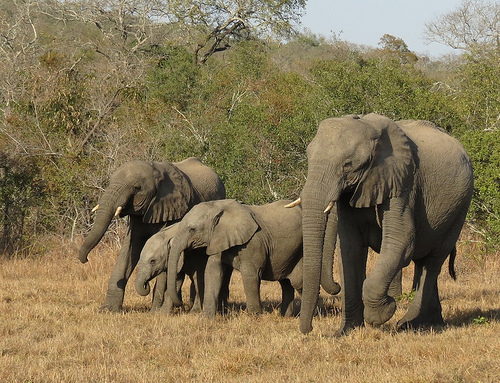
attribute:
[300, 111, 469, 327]
wrinkly elephant — gray, walking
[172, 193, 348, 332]
elephant walking — gray, wrinkly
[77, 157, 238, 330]
grey elephant — wrinkly, gray, walking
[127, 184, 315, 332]
an elephant walking — gray, wrinkly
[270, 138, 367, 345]
elephant trunk — long, gray, wrinkly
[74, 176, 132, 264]
long elephant trunk — wrinkly, gray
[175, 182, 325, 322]
wrinkly elephant — gray, long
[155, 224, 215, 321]
long grey trunk — wrinkly, gray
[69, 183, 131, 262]
grey wrinkly trunk — gray, long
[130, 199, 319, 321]
baby elephants — standing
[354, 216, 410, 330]
leg of elephant — raised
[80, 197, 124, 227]
with two tusks — small elephants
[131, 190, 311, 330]
elephant in middle — baby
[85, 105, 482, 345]
herd of — four elephants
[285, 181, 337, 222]
two white tusks — elephant tusks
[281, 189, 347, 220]
two white tusks — elephant tusks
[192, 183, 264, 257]
large gray ear — elephant's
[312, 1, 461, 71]
gray sky — light blue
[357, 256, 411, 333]
foot lifted — Elephant's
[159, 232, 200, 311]
gray elephant trunk — long